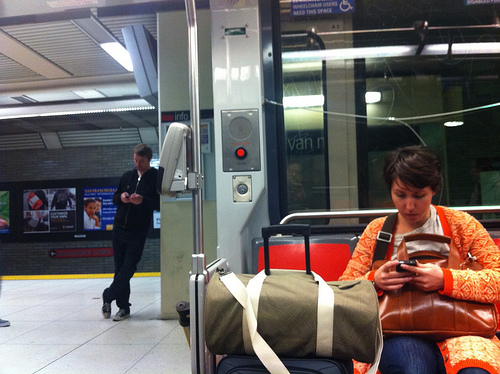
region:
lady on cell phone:
[336, 160, 498, 370]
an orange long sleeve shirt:
[350, 200, 499, 369]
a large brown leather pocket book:
[382, 230, 495, 334]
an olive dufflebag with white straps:
[202, 263, 386, 372]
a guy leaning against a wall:
[97, 144, 160, 325]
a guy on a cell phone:
[99, 147, 158, 318]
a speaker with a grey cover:
[222, 108, 259, 173]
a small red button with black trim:
[232, 144, 250, 159]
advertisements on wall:
[1, 180, 160, 230]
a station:
[1, 3, 499, 369]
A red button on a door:
[235, 142, 247, 154]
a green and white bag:
[227, 261, 258, 294]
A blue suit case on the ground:
[203, 354, 247, 372]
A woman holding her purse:
[405, 323, 437, 346]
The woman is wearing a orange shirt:
[469, 211, 492, 235]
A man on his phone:
[97, 183, 140, 205]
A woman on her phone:
[387, 255, 418, 277]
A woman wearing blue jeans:
[362, 359, 402, 372]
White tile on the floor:
[79, 329, 103, 356]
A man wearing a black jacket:
[119, 167, 134, 179]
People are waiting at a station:
[5, 28, 496, 366]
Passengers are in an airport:
[16, 31, 489, 371]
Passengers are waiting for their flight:
[26, 52, 494, 370]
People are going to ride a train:
[15, 75, 486, 371]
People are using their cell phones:
[21, 25, 496, 370]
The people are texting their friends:
[15, 65, 495, 361]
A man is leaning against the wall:
[56, 38, 176, 370]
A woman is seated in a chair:
[205, 70, 496, 370]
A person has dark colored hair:
[377, 140, 445, 225]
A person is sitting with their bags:
[197, 141, 499, 372]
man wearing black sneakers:
[96, 145, 158, 318]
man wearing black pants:
[96, 145, 156, 319]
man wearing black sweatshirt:
[97, 143, 157, 317]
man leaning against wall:
[100, 148, 164, 318]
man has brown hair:
[130, 145, 151, 169]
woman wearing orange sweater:
[335, 153, 497, 370]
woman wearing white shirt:
[340, 150, 498, 372]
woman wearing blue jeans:
[340, 147, 496, 369]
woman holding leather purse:
[339, 150, 495, 368]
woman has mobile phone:
[333, 152, 498, 370]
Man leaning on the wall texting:
[98, 140, 161, 325]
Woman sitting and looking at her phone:
[335, 141, 498, 372]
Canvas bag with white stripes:
[202, 265, 380, 370]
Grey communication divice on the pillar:
[215, 107, 265, 174]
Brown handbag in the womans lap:
[368, 230, 498, 339]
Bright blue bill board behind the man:
[80, 182, 119, 233]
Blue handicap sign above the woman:
[287, 0, 359, 22]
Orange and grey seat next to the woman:
[247, 230, 360, 287]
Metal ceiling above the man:
[0, 0, 152, 82]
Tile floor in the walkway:
[1, 276, 192, 372]